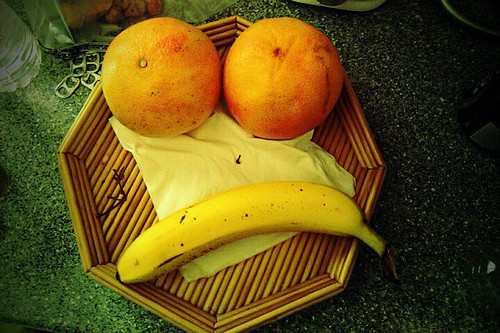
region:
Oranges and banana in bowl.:
[56, 16, 398, 331]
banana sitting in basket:
[93, 169, 403, 298]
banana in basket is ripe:
[99, 174, 407, 297]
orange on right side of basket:
[218, 13, 340, 140]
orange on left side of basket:
[98, 13, 228, 144]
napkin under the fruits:
[109, 94, 369, 282]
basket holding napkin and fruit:
[33, 9, 405, 332]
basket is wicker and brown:
[38, 12, 408, 332]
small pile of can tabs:
[43, 40, 111, 110]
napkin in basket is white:
[98, 94, 372, 284]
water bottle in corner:
[1, 2, 45, 98]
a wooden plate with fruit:
[58, 15, 383, 331]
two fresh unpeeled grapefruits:
[100, 15, 345, 135]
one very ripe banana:
[111, 180, 396, 285]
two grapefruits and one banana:
[100, 12, 401, 284]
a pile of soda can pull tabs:
[51, 47, 97, 92]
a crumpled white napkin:
[105, 110, 352, 275]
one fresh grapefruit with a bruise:
[220, 15, 340, 137]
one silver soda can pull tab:
[50, 70, 75, 96]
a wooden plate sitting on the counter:
[53, 15, 390, 332]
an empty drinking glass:
[0, 0, 44, 94]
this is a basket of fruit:
[49, 10, 400, 330]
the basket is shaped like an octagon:
[25, 2, 397, 331]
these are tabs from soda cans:
[45, 45, 107, 98]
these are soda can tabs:
[55, 47, 112, 102]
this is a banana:
[105, 166, 401, 283]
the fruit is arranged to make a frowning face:
[39, 2, 398, 332]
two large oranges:
[96, 8, 341, 158]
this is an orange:
[100, 15, 220, 142]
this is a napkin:
[109, 109, 359, 285]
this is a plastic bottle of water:
[0, 1, 42, 94]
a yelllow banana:
[112, 158, 403, 314]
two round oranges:
[100, 15, 340, 135]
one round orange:
[217, 15, 342, 140]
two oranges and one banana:
[51, 12, 393, 328]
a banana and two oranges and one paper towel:
[60, 15, 395, 330]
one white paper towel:
[110, 91, 355, 277]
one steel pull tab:
[51, 70, 76, 100]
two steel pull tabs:
[51, 45, 81, 100]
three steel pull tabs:
[71, 46, 98, 92]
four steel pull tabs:
[53, 48, 100, 109]